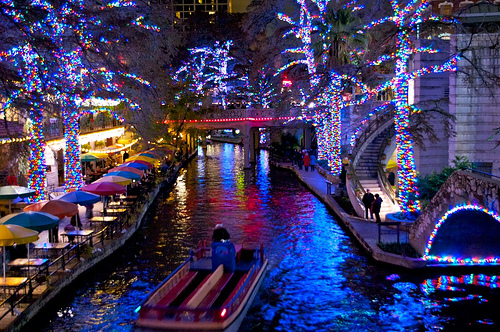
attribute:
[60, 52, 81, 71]
lights — colorful, blue, red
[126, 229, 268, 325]
boat — traveling, small, empty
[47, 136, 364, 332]
canal — winding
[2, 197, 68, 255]
umbrellas — colorful, blue, red, green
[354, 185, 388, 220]
people — walking, standing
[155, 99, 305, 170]
bridge — decorated, lit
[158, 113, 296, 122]
light — strung, red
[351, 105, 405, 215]
stairs — large, curved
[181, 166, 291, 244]
water — reflecting, dark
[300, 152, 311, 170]
lady — walking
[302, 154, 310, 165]
coat — red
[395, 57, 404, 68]
lights — red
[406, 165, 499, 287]
entrance — lit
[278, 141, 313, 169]
people — walking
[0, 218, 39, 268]
umbrella — yellow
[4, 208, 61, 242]
umbrella — blue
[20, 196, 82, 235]
umbrella — red